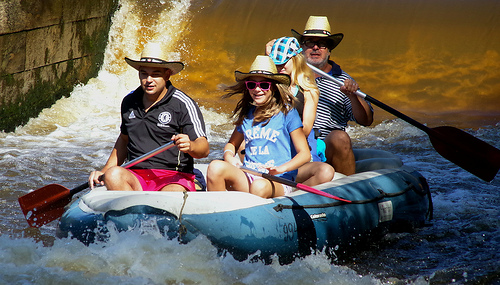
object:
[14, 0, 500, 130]
brown water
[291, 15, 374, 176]
man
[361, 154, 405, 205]
ground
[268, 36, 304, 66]
helmet.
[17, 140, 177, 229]
paddle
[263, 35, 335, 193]
girl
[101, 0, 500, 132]
waterfall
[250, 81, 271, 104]
face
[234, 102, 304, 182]
shirt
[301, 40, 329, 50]
black sunglasses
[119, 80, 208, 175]
black shirt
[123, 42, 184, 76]
cowboy hat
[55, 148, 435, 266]
boat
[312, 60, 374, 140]
shirt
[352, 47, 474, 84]
water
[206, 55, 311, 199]
girl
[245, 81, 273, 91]
glasses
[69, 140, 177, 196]
handle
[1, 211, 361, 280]
water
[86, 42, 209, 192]
he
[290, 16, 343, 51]
cowboy hat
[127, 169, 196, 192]
shorts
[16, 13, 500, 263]
water rafting